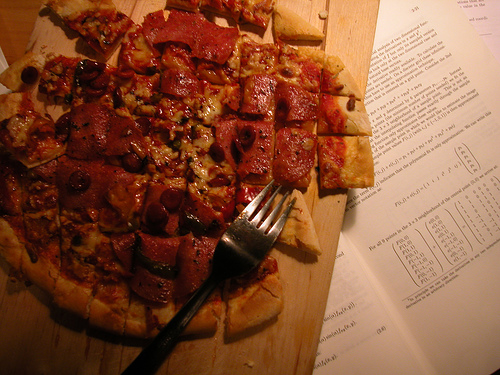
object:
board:
[0, 1, 381, 374]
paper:
[312, 0, 500, 375]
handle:
[119, 278, 222, 374]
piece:
[41, 0, 136, 61]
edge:
[316, 54, 376, 192]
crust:
[275, 14, 378, 187]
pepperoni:
[65, 102, 143, 160]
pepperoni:
[215, 114, 274, 180]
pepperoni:
[143, 9, 240, 64]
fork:
[117, 178, 298, 373]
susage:
[313, 92, 374, 136]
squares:
[318, 135, 376, 190]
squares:
[40, 52, 83, 100]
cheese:
[11, 0, 304, 297]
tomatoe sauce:
[319, 67, 347, 190]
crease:
[342, 228, 439, 374]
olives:
[69, 170, 93, 192]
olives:
[240, 124, 257, 145]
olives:
[160, 188, 182, 211]